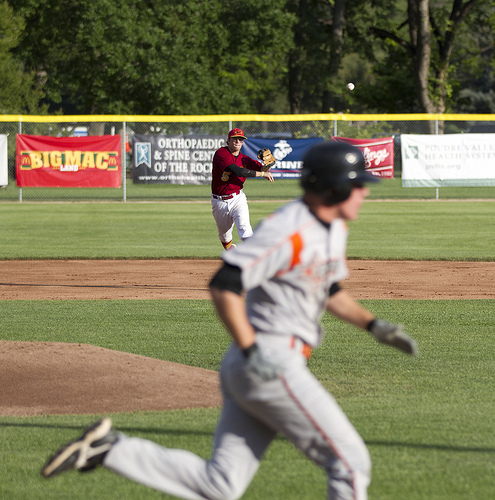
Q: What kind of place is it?
A: It is a field.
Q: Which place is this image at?
A: It is at the field.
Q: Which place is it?
A: It is a field.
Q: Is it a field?
A: Yes, it is a field.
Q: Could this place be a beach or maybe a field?
A: It is a field.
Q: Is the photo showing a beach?
A: No, the picture is showing a field.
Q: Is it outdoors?
A: Yes, it is outdoors.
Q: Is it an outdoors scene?
A: Yes, it is outdoors.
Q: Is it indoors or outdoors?
A: It is outdoors.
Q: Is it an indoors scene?
A: No, it is outdoors.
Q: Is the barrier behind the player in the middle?
A: Yes, the barrier is behind the player.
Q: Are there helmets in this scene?
A: Yes, there is a helmet.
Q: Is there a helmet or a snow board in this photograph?
A: Yes, there is a helmet.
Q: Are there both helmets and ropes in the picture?
A: No, there is a helmet but no ropes.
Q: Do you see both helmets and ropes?
A: No, there is a helmet but no ropes.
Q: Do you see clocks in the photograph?
A: No, there are no clocks.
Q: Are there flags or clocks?
A: No, there are no clocks or flags.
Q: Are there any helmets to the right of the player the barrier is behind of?
A: Yes, there is a helmet to the right of the player.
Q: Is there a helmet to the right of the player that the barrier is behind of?
A: Yes, there is a helmet to the right of the player.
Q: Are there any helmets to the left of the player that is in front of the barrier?
A: No, the helmet is to the right of the player.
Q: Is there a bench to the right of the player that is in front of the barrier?
A: No, there is a helmet to the right of the player.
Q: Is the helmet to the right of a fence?
A: No, the helmet is to the right of the player.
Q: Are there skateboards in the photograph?
A: No, there are no skateboards.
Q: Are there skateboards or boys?
A: No, there are no skateboards or boys.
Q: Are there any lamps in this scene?
A: No, there are no lamps.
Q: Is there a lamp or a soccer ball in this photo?
A: No, there are no lamps or soccer balls.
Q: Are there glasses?
A: No, there are no glasses.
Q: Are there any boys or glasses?
A: No, there are no glasses or boys.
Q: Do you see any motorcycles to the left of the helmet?
A: No, there is a player to the left of the helmet.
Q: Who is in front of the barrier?
A: The player is in front of the barrier.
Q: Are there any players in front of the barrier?
A: Yes, there is a player in front of the barrier.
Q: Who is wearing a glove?
A: The player is wearing a glove.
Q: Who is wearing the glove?
A: The player is wearing a glove.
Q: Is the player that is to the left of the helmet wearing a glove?
A: Yes, the player is wearing a glove.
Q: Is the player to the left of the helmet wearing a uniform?
A: No, the player is wearing a glove.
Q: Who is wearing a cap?
A: The player is wearing a cap.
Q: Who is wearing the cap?
A: The player is wearing a cap.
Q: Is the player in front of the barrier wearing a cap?
A: Yes, the player is wearing a cap.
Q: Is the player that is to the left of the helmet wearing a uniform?
A: No, the player is wearing a cap.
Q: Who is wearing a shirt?
A: The player is wearing a shirt.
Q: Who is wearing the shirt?
A: The player is wearing a shirt.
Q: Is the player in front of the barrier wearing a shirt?
A: Yes, the player is wearing a shirt.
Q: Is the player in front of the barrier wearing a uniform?
A: No, the player is wearing a shirt.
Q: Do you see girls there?
A: No, there are no girls.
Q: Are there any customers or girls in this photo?
A: No, there are no girls or customers.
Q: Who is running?
A: The player is running.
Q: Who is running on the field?
A: The player is running on the field.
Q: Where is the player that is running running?
A: The player is running on the field.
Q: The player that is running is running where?
A: The player is running on the field.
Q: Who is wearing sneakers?
A: The player is wearing sneakers.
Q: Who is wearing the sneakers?
A: The player is wearing sneakers.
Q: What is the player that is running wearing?
A: The player is wearing sneakers.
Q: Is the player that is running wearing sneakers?
A: Yes, the player is wearing sneakers.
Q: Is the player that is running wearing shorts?
A: No, the player is wearing sneakers.